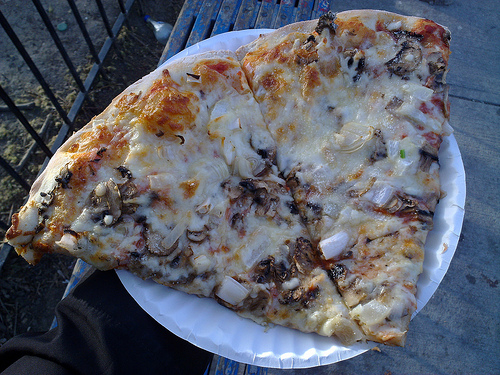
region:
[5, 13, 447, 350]
Two pieces of pizza on a paper plate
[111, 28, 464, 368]
White paper plate holding pizza pieces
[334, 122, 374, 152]
A piece of onion topping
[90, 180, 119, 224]
Olive pice in the topping of pizza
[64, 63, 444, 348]
Cheese on the pizza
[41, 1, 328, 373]
Part of blue bench visible on both sides of the plate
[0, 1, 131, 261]
Railing of metal vertical rods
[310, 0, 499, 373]
Cemented floor under the bench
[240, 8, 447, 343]
One triangular piece of pizza on the right side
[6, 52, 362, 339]
One triangular piece of pizza on the left side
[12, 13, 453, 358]
two slices of pizza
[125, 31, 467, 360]
white paper plate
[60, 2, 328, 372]
old blue bench with paint peeling off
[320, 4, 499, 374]
gray concrete sidewalk below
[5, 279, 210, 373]
black jacket on an arm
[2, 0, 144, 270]
black metal fence on the left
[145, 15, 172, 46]
empty plastic bottle on the ground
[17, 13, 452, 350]
two slices of mushroom pizza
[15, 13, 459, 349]
giant slices of pizza on a white plate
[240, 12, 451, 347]
the slice of pizza on the right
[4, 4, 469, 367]
Two slices of delicious pizza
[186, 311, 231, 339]
Part of white paper plate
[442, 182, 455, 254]
Part of white paper plate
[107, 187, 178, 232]
Part of delicious pizza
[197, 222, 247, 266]
Part of delicious pizza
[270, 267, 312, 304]
Part of delicious pizza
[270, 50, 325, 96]
Part of delicious pizza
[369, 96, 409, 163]
Part of delicious pizza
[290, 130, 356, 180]
Part of delicious pizza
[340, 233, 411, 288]
Part of delicious pizza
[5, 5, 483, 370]
two slices of pizza on a plate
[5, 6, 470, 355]
pizza is bigger than the plate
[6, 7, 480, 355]
pizza has cheese on it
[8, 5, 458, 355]
pizza has onion on it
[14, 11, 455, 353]
pizza has mushroom on it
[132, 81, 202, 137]
bubble on the pizza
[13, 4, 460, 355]
pizza with mushrooms on it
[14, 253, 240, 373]
person's arm holding the plate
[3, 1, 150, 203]
black metal fence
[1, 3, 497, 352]
Two Large Slices Of Pizza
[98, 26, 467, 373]
White Paper Plate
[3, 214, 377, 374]
Hand Holding The Plate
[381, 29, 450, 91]
Mushroom pieces on the pizza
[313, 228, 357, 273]
Chunks of onion on the pizza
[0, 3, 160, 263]
Black Cast Iron Fence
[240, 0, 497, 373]
Smooth Grey Concrete Sidewalk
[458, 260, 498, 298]
Wet marks on the concrete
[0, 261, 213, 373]
Black Shirt Material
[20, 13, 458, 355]
Pizza loaded with cheese